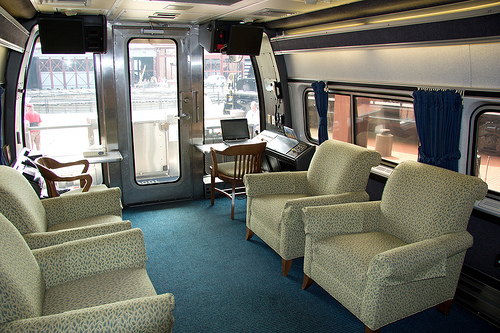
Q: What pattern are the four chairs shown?
A: Speckled.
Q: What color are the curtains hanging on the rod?
A: Blue.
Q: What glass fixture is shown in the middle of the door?
A: Window.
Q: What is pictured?
A: A remodeled bus as a living room.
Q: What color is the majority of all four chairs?
A: Yellow.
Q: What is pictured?
A: Front door.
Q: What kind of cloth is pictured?
A: Curtains.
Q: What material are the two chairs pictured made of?
A: Wood.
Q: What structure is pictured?
A: A chair.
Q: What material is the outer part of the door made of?
A: Metal.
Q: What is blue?
A: Carpet.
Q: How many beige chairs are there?
A: Four.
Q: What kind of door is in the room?
A: Silver door.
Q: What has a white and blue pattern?
A: A chair.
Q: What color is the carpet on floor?
A: Blue.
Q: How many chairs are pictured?
A: Six.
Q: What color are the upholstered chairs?
A: Cream.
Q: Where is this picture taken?
A: A train.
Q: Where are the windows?
A: Behind the chairs.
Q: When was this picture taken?
A: During the day.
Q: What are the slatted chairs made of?
A: Wood.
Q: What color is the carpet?
A: Blue.